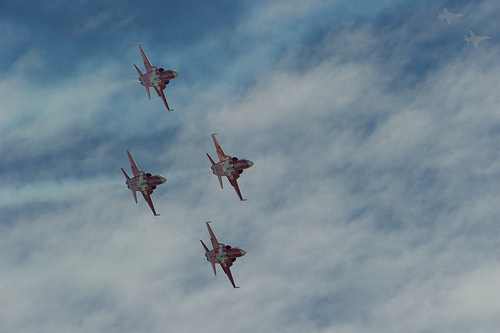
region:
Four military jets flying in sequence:
[117, 43, 254, 288]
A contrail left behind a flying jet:
[2, 166, 207, 207]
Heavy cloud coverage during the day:
[1, 2, 498, 330]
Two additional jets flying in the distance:
[435, 7, 491, 50]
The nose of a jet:
[236, 248, 246, 255]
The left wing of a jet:
[204, 223, 221, 248]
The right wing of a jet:
[222, 269, 240, 291]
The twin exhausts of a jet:
[200, 251, 212, 265]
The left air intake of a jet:
[223, 245, 233, 250]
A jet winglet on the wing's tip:
[232, 284, 239, 289]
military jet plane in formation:
[125, 45, 190, 110]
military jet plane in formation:
[102, 130, 182, 234]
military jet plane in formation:
[197, 120, 256, 192]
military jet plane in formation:
[202, 208, 257, 286]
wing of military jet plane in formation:
[202, 218, 222, 247]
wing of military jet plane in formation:
[212, 134, 226, 156]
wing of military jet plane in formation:
[124, 144, 144, 170]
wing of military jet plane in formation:
[132, 45, 152, 65]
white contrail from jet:
[0, 180, 125, 210]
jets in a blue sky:
[117, 42, 267, 295]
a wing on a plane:
[226, 268, 242, 296]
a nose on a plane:
[237, 246, 246, 257]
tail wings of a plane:
[197, 238, 221, 278]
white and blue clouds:
[313, 0, 495, 216]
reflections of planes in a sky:
[425, 1, 495, 66]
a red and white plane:
[196, 216, 246, 287]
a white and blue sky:
[330, 97, 496, 306]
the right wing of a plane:
[149, 196, 161, 220]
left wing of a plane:
[123, 146, 143, 173]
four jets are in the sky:
[111, 37, 270, 301]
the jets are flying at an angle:
[117, 30, 272, 293]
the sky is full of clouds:
[16, 3, 493, 323]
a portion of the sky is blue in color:
[3, 4, 364, 51]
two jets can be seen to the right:
[423, 5, 496, 57]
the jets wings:
[138, 44, 173, 111]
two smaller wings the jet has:
[206, 149, 223, 192]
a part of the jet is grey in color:
[219, 132, 236, 210]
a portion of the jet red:
[211, 136, 225, 191]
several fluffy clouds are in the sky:
[271, 55, 486, 322]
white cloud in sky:
[41, 247, 71, 285]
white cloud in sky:
[19, 186, 76, 220]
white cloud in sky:
[25, 113, 70, 147]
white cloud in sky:
[67, 52, 116, 108]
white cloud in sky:
[222, 89, 312, 156]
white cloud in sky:
[288, 64, 355, 113]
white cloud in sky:
[406, 42, 475, 122]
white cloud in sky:
[417, 125, 472, 181]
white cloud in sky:
[342, 136, 428, 223]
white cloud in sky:
[305, 239, 365, 277]